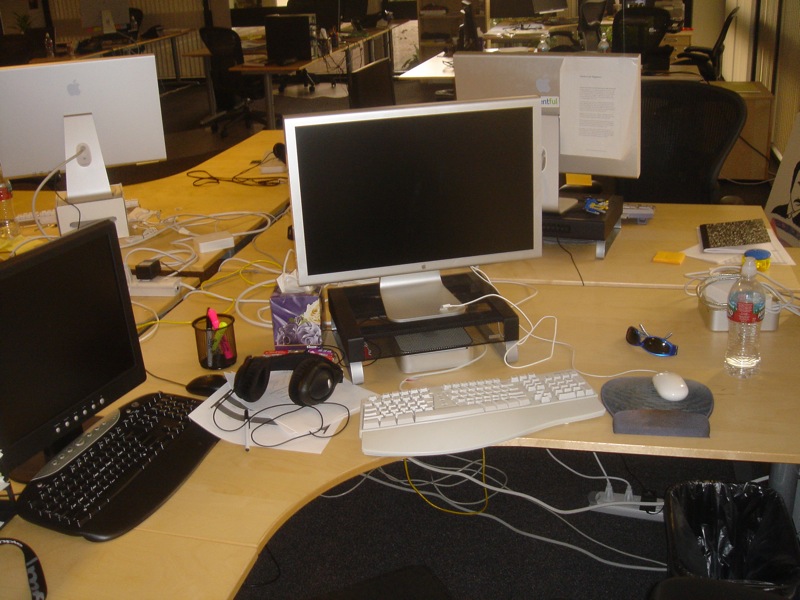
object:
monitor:
[0, 220, 223, 542]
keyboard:
[18, 393, 220, 541]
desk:
[0, 128, 800, 600]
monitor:
[278, 98, 541, 291]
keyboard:
[359, 370, 608, 456]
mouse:
[654, 371, 690, 402]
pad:
[599, 370, 713, 438]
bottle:
[724, 255, 767, 379]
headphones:
[233, 351, 345, 406]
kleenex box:
[270, 282, 325, 351]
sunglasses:
[625, 323, 678, 357]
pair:
[624, 324, 679, 357]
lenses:
[642, 337, 669, 355]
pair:
[233, 353, 344, 407]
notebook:
[698, 218, 771, 254]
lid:
[741, 257, 757, 278]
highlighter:
[206, 308, 236, 367]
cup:
[191, 313, 237, 370]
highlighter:
[206, 320, 213, 368]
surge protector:
[127, 262, 182, 297]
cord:
[135, 259, 161, 280]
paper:
[188, 365, 379, 456]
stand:
[327, 270, 519, 363]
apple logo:
[66, 78, 81, 95]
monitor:
[0, 55, 171, 176]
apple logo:
[535, 74, 552, 94]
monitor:
[447, 48, 645, 181]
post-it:
[566, 172, 593, 186]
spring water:
[727, 318, 757, 369]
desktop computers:
[0, 55, 645, 352]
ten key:
[363, 370, 596, 429]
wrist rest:
[614, 409, 710, 438]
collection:
[0, 51, 720, 545]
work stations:
[0, 56, 655, 540]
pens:
[203, 307, 235, 367]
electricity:
[124, 227, 234, 298]